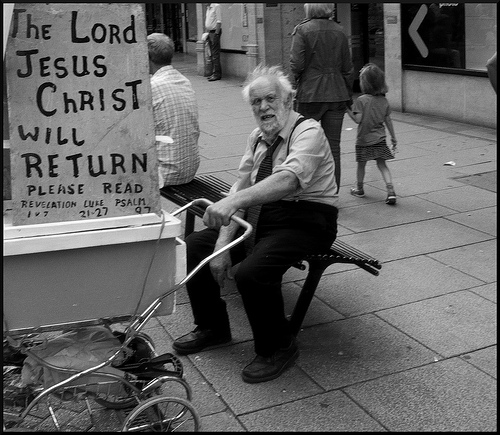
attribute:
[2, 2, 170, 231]
sign — large, black, white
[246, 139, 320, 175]
shirt — white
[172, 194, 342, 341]
pants — black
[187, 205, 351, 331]
pants — black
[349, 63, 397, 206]
girl — young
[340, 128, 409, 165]
skirt — girl's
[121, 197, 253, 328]
handle — silver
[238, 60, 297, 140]
head — man's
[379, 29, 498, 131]
building — brick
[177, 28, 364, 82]
building — brick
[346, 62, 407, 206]
girl — little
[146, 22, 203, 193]
man — sitting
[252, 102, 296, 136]
beard — white, man's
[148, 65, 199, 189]
man`s shirt — plaid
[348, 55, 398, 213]
girl — walking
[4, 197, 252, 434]
carriage — baby 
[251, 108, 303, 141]
neck — man's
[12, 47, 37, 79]
letter — black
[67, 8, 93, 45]
letter — black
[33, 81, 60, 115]
letter — black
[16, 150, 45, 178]
letter — black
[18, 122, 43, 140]
letter — black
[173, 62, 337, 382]
man — sitting